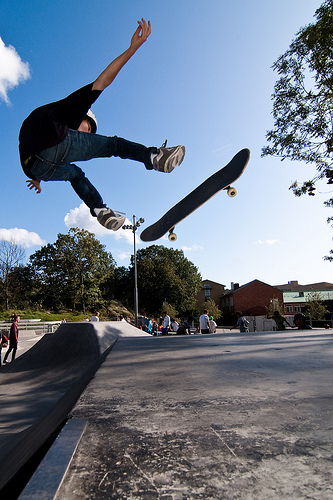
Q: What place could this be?
A: It is a park.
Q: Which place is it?
A: It is a park.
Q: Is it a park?
A: Yes, it is a park.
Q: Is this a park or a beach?
A: It is a park.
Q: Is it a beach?
A: No, it is a park.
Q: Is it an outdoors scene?
A: Yes, it is outdoors.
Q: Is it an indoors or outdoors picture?
A: It is outdoors.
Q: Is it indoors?
A: No, it is outdoors.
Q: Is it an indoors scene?
A: No, it is outdoors.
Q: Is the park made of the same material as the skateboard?
A: No, the park is made of cement and the skateboard is made of wood.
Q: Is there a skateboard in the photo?
A: Yes, there is a skateboard.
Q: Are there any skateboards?
A: Yes, there is a skateboard.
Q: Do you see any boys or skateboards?
A: Yes, there is a skateboard.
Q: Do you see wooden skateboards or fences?
A: Yes, there is a wood skateboard.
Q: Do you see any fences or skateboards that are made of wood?
A: Yes, the skateboard is made of wood.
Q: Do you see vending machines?
A: No, there are no vending machines.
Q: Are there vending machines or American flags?
A: No, there are no vending machines or American flags.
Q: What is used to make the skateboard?
A: The skateboard is made of wood.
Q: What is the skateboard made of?
A: The skateboard is made of wood.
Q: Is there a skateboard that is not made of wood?
A: No, there is a skateboard but it is made of wood.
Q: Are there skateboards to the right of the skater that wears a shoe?
A: Yes, there is a skateboard to the right of the skater.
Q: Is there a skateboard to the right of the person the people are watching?
A: Yes, there is a skateboard to the right of the skater.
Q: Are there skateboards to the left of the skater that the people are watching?
A: No, the skateboard is to the right of the skater.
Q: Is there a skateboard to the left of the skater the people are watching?
A: No, the skateboard is to the right of the skater.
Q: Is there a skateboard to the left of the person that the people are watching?
A: No, the skateboard is to the right of the skater.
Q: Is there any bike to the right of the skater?
A: No, there is a skateboard to the right of the skater.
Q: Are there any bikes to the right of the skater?
A: No, there is a skateboard to the right of the skater.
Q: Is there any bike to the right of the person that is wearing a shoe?
A: No, there is a skateboard to the right of the skater.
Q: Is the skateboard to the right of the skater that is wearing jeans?
A: Yes, the skateboard is to the right of the skater.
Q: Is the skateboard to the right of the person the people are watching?
A: Yes, the skateboard is to the right of the skater.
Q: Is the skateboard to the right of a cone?
A: No, the skateboard is to the right of the skater.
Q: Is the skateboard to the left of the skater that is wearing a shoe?
A: No, the skateboard is to the right of the skater.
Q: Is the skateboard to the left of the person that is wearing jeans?
A: No, the skateboard is to the right of the skater.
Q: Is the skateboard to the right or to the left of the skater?
A: The skateboard is to the right of the skater.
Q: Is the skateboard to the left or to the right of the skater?
A: The skateboard is to the right of the skater.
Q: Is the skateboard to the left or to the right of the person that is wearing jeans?
A: The skateboard is to the right of the skater.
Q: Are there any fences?
A: No, there are no fences.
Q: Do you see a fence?
A: No, there are no fences.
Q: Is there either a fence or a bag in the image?
A: No, there are no fences or bags.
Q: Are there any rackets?
A: No, there are no rackets.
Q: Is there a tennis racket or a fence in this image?
A: No, there are no rackets or fences.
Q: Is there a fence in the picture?
A: No, there are no fences.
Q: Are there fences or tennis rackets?
A: No, there are no fences or tennis rackets.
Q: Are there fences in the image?
A: No, there are no fences.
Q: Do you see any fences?
A: No, there are no fences.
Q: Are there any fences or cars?
A: No, there are no fences or cars.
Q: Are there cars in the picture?
A: No, there are no cars.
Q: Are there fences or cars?
A: No, there are no cars or fences.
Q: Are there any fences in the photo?
A: No, there are no fences.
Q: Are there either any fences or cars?
A: No, there are no cars or fences.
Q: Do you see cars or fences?
A: No, there are no cars or fences.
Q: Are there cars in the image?
A: No, there are no cars.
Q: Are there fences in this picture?
A: No, there are no fences.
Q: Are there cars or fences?
A: No, there are no fences or cars.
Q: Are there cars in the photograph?
A: No, there are no cars.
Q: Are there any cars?
A: No, there are no cars.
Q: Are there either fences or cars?
A: No, there are no cars or fences.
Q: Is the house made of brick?
A: Yes, the house is made of brick.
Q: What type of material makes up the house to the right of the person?
A: The house is made of brick.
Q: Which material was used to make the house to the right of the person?
A: The house is made of brick.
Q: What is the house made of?
A: The house is made of brick.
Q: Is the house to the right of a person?
A: Yes, the house is to the right of a person.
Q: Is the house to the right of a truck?
A: No, the house is to the right of a person.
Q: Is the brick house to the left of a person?
A: No, the house is to the right of a person.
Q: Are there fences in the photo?
A: No, there are no fences.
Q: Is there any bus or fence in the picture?
A: No, there are no fences or buses.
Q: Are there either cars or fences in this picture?
A: No, there are no fences or cars.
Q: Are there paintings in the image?
A: No, there are no paintings.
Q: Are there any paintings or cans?
A: No, there are no paintings or cans.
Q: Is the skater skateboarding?
A: Yes, the skater is skateboarding.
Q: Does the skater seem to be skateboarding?
A: Yes, the skater is skateboarding.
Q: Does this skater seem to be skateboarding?
A: Yes, the skater is skateboarding.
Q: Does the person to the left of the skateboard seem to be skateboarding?
A: Yes, the skater is skateboarding.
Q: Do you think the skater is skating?
A: No, the skater is skateboarding.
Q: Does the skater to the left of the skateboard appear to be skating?
A: No, the skater is skateboarding.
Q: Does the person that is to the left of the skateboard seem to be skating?
A: No, the skater is skateboarding.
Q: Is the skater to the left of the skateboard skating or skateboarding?
A: The skater is skateboarding.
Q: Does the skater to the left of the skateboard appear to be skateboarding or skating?
A: The skater is skateboarding.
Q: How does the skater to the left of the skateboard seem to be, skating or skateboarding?
A: The skater is skateboarding.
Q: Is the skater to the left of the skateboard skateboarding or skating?
A: The skater is skateboarding.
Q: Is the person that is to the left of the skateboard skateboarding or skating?
A: The skater is skateboarding.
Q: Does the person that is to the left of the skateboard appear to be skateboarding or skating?
A: The skater is skateboarding.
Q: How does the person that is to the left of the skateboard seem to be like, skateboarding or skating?
A: The skater is skateboarding.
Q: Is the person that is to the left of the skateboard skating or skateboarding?
A: The skater is skateboarding.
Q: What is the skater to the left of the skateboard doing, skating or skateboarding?
A: The skater is skateboarding.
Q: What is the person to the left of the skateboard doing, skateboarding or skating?
A: The skater is skateboarding.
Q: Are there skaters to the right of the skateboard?
A: No, the skater is to the left of the skateboard.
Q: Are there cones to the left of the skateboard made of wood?
A: No, there is a skater to the left of the skateboard.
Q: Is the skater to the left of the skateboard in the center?
A: Yes, the skater is to the left of the skateboard.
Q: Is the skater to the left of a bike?
A: No, the skater is to the left of the skateboard.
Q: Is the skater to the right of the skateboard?
A: No, the skater is to the left of the skateboard.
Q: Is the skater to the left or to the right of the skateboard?
A: The skater is to the left of the skateboard.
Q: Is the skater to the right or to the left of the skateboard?
A: The skater is to the left of the skateboard.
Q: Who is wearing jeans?
A: The skater is wearing jeans.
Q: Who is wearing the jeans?
A: The skater is wearing jeans.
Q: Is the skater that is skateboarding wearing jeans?
A: Yes, the skater is wearing jeans.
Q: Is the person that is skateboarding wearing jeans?
A: Yes, the skater is wearing jeans.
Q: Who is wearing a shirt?
A: The skater is wearing a shirt.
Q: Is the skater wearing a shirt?
A: Yes, the skater is wearing a shirt.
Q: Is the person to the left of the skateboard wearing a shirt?
A: Yes, the skater is wearing a shirt.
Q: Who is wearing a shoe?
A: The skater is wearing a shoe.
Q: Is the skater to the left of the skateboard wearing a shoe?
A: Yes, the skater is wearing a shoe.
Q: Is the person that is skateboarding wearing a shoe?
A: Yes, the skater is wearing a shoe.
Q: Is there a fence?
A: No, there are no fences.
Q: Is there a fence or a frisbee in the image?
A: No, there are no fences or frisbees.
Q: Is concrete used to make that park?
A: Yes, the park is made of concrete.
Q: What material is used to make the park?
A: The park is made of concrete.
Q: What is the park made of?
A: The park is made of concrete.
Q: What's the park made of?
A: The park is made of concrete.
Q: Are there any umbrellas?
A: No, there are no umbrellas.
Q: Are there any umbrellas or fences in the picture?
A: No, there are no umbrellas or fences.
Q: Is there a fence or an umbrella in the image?
A: No, there are no umbrellas or fences.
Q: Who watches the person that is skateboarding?
A: The people watch the skater.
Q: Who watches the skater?
A: The people watch the skater.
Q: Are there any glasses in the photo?
A: No, there are no glasses.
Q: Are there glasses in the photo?
A: No, there are no glasses.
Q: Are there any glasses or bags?
A: No, there are no glasses or bags.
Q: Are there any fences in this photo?
A: No, there are no fences.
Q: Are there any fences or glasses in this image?
A: No, there are no fences or glasses.